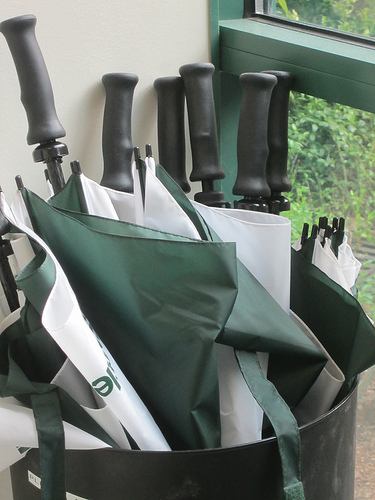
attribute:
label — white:
[27, 473, 93, 498]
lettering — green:
[88, 323, 123, 409]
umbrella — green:
[81, 222, 172, 272]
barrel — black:
[13, 388, 361, 495]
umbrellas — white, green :
[17, 191, 292, 414]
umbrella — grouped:
[26, 109, 313, 435]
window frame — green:
[204, 0, 373, 223]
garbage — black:
[42, 328, 369, 496]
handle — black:
[78, 64, 159, 194]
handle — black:
[1, 13, 67, 139]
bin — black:
[86, 428, 374, 497]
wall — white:
[0, 0, 213, 206]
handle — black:
[1, 15, 63, 145]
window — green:
[250, 0, 373, 317]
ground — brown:
[360, 432, 371, 456]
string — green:
[229, 344, 307, 497]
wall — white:
[1, 1, 211, 228]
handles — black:
[242, 69, 315, 210]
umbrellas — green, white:
[35, 178, 332, 438]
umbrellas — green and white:
[29, 139, 368, 471]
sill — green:
[211, 13, 374, 113]